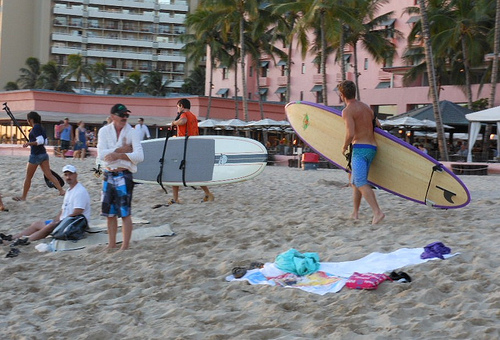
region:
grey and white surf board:
[141, 136, 266, 185]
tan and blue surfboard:
[289, 100, 470, 220]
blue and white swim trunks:
[105, 171, 135, 218]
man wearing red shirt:
[165, 98, 215, 203]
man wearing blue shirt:
[58, 118, 73, 153]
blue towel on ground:
[276, 249, 318, 275]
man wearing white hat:
[52, 166, 93, 236]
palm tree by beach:
[208, 1, 278, 164]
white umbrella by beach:
[383, 115, 423, 130]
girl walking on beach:
[20, 112, 62, 201]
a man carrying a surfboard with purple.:
[285, 77, 470, 228]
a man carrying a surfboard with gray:
[138, 97, 270, 194]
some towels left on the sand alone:
[227, 240, 464, 306]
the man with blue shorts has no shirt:
[325, 79, 386, 233]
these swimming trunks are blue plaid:
[95, 170, 134, 224]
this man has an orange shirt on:
[174, 109, 196, 136]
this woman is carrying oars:
[3, 100, 63, 202]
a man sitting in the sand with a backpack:
[13, 163, 95, 249]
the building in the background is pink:
[200, 45, 495, 102]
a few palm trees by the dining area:
[181, 0, 408, 106]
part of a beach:
[136, 283, 158, 303]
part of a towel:
[370, 270, 381, 279]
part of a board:
[432, 154, 459, 191]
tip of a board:
[313, 105, 318, 119]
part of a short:
[101, 175, 116, 210]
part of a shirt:
[78, 198, 104, 199]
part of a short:
[336, 165, 368, 203]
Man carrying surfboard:
[280, 79, 471, 231]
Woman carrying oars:
[0, 99, 62, 199]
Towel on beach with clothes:
[227, 240, 457, 298]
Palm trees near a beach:
[191, 2, 396, 69]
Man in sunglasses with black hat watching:
[94, 101, 144, 252]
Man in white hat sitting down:
[17, 163, 89, 250]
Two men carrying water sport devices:
[147, 79, 471, 229]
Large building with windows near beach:
[0, 1, 192, 90]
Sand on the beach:
[5, 263, 221, 335]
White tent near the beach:
[463, 101, 498, 163]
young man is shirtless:
[337, 79, 385, 225]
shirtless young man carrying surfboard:
[285, 80, 470, 226]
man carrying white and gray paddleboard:
[132, 98, 267, 186]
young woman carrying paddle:
[1, 100, 65, 202]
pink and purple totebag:
[345, 271, 391, 293]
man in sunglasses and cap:
[94, 103, 146, 250]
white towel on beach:
[224, 244, 461, 295]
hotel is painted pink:
[1, 0, 498, 173]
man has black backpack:
[0, 164, 91, 250]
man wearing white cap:
[1, 163, 91, 245]